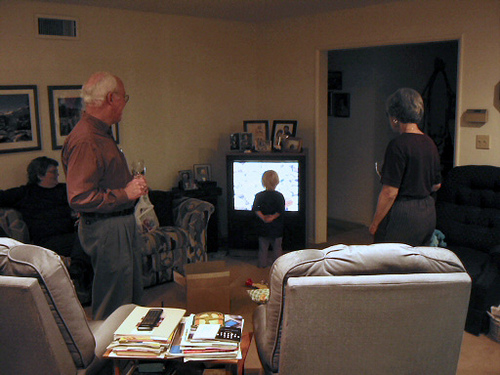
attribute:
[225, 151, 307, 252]
television — black, large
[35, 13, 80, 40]
vent — silver, white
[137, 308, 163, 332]
remote control — black, long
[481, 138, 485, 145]
light switch — beige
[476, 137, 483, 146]
light switch — beige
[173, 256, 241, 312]
cardboard box — open, brown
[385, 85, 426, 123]
hair — gray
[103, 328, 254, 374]
table — brown, covered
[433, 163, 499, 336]
chair — large, black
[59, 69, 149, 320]
man — standing, balding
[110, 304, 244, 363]
books — stacked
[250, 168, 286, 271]
boy — blonde, small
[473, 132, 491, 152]
switch panel — white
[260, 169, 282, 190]
hair — short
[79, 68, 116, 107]
hair — white, grey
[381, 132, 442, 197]
shirt — black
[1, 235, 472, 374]
chairs — grey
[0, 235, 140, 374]
chair — reclining, large, gray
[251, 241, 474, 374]
chair — gray, reclining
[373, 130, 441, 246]
outfit — black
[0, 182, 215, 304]
couch — multicolored